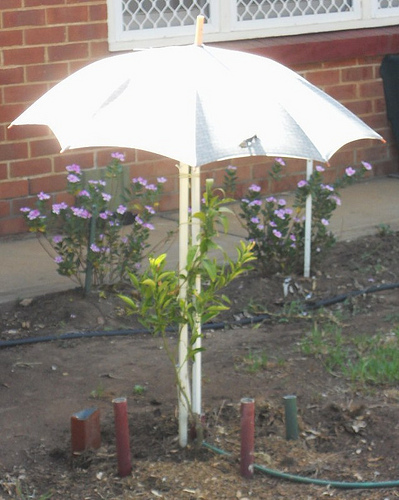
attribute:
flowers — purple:
[60, 152, 189, 281]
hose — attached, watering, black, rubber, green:
[214, 418, 326, 462]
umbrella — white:
[94, 74, 262, 168]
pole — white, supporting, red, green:
[87, 407, 134, 454]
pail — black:
[368, 46, 397, 140]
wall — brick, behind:
[10, 28, 69, 72]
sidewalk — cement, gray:
[4, 247, 95, 306]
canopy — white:
[55, 88, 89, 129]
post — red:
[210, 367, 276, 461]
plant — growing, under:
[90, 191, 192, 331]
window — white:
[212, 5, 329, 33]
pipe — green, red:
[272, 392, 328, 436]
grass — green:
[292, 315, 393, 362]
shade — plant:
[50, 291, 182, 408]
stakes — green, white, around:
[272, 177, 348, 273]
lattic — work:
[95, 16, 153, 28]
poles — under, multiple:
[144, 180, 214, 259]